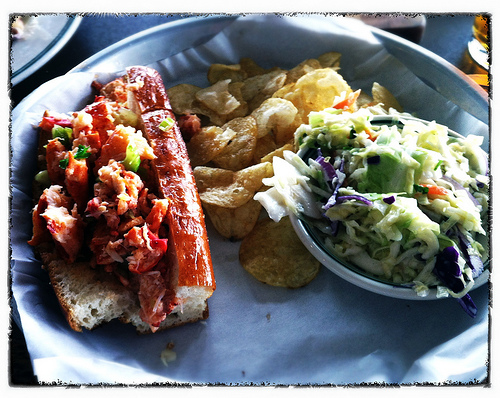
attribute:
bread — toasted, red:
[120, 70, 212, 333]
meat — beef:
[99, 185, 161, 278]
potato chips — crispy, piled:
[190, 58, 319, 268]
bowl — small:
[287, 122, 492, 301]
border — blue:
[16, 19, 139, 78]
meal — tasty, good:
[32, 84, 493, 323]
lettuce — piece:
[370, 160, 417, 214]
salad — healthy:
[305, 120, 487, 282]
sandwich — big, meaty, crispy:
[37, 79, 207, 327]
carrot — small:
[419, 183, 450, 199]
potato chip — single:
[233, 227, 326, 294]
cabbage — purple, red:
[314, 162, 370, 219]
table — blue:
[26, 17, 498, 285]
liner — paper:
[149, 31, 437, 97]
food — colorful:
[37, 52, 499, 331]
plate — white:
[21, 16, 484, 381]